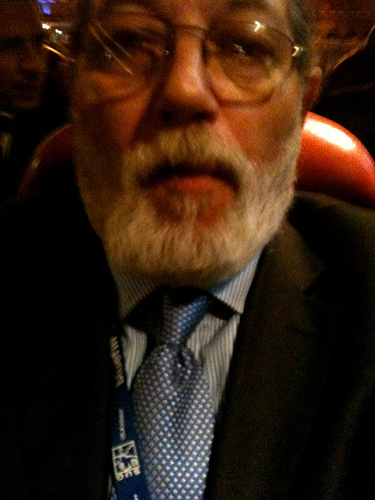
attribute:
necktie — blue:
[103, 285, 217, 498]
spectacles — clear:
[85, 24, 302, 111]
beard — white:
[75, 132, 302, 289]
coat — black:
[0, 178, 372, 498]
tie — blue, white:
[111, 304, 240, 493]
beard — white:
[50, 83, 326, 274]